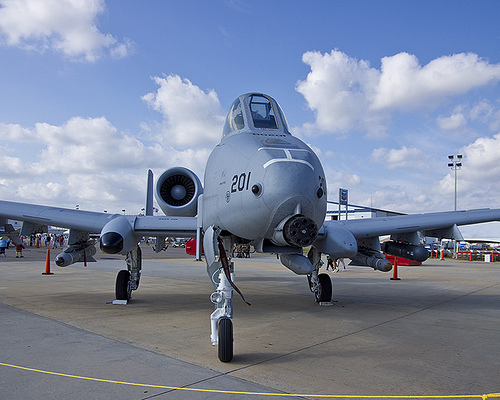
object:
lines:
[256, 147, 317, 171]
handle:
[218, 312, 233, 317]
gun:
[286, 217, 319, 247]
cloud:
[2, 0, 134, 61]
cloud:
[142, 74, 224, 148]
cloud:
[295, 50, 376, 137]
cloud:
[375, 51, 495, 106]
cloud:
[440, 114, 464, 132]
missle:
[55, 237, 98, 267]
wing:
[0, 200, 199, 263]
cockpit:
[224, 91, 284, 135]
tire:
[114, 267, 131, 304]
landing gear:
[113, 244, 142, 301]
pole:
[447, 154, 462, 211]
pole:
[453, 240, 456, 255]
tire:
[217, 317, 234, 363]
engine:
[153, 165, 201, 217]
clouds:
[2, 73, 228, 217]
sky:
[3, 1, 499, 242]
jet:
[0, 90, 500, 368]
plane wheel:
[314, 273, 333, 304]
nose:
[222, 139, 329, 239]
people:
[14, 238, 24, 258]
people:
[13, 257, 20, 283]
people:
[43, 234, 48, 247]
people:
[52, 234, 58, 249]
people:
[60, 235, 64, 246]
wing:
[325, 208, 500, 256]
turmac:
[53, 303, 313, 396]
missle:
[353, 252, 393, 273]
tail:
[145, 169, 156, 216]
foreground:
[0, 90, 500, 369]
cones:
[40, 248, 55, 275]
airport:
[0, 240, 500, 400]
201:
[230, 171, 251, 193]